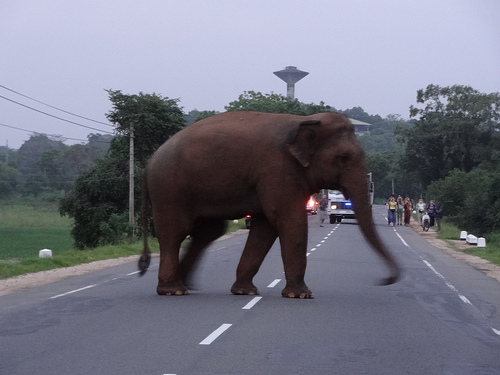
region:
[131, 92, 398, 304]
large brown adult elephant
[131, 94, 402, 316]
elephant walking across the road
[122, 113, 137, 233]
tall silver metal wire pole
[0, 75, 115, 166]
black wires suspended in the air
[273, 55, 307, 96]
saucer shaped tower in the background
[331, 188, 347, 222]
white truck on the road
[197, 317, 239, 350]
dotted white lines on the road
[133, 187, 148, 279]
brown tail of the elephant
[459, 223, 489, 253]
white objects at the side of the road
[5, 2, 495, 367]
elephant walking on a paved street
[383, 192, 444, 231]
six people on the side of a two lane road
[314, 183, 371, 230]
man standing in the road next to an RV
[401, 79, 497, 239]
green trees on the side of the road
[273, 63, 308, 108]
gray tower showing over the tree tops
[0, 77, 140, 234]
utility pole and wires on the side of the road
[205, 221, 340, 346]
white painted stripes on the pavement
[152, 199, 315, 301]
legs of the elephant with flat feet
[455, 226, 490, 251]
white painted blocks on the side of the road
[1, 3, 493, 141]
gray overcast sky over tree tops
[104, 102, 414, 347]
An elephant crossing the street.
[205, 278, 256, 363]
White lines in the street.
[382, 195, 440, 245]
People walking on the street.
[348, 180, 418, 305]
The elephant trunk is curved.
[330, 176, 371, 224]
A vehicle on the street.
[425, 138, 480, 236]
Bushes next to the people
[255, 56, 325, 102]
A tower in the background.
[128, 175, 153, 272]
The elephant has a long tail.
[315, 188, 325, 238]
A man in the street.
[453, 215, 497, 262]
White posts on the side of the road.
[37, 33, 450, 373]
this is an elephant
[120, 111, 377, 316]
the elephant is brown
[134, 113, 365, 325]
the elephant has a trunk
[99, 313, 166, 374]
the pavement is gray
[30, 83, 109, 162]
these are power lines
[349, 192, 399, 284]
trunk of the elephant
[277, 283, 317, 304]
foot of the elephant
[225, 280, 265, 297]
foot of the elephant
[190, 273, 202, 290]
foot of the elephant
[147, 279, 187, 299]
foot of the elephant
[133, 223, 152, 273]
tail of the elephant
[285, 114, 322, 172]
ear of the elephant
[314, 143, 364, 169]
eye of the elephant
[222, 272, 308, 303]
front legs of elephant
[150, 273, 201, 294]
back legs of elephant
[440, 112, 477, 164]
green leaves on the tree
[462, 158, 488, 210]
green leaves on the tree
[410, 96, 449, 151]
green leaves on the tree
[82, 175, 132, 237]
green leaves on the tree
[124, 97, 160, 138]
green leaves on the tree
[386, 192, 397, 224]
woman in yellow shirt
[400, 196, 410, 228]
woman in red shirt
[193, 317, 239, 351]
white line on street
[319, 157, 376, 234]
white van on street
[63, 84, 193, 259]
tall green tree on side of road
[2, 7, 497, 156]
overcast cloudy sky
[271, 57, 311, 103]
metal building poking on top of the trees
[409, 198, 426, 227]
person in white walking on side of the road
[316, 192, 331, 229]
man crossing the street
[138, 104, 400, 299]
a large grey elephant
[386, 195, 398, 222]
a person walking on a street